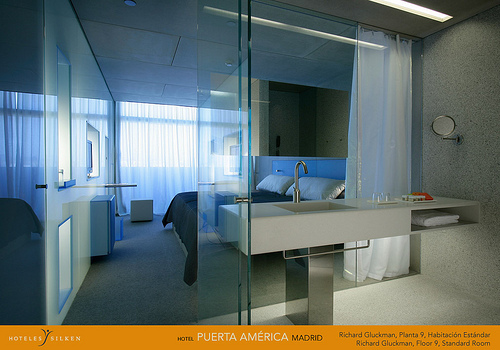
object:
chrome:
[293, 160, 309, 204]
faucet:
[292, 160, 308, 203]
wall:
[447, 50, 480, 78]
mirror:
[432, 115, 456, 135]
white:
[412, 210, 460, 227]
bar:
[283, 239, 370, 259]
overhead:
[376, 26, 450, 46]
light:
[370, 0, 454, 23]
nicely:
[177, 193, 266, 233]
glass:
[208, 16, 261, 70]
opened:
[195, 26, 246, 230]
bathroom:
[250, 56, 500, 325]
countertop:
[357, 198, 404, 208]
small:
[430, 115, 456, 138]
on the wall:
[429, 116, 464, 146]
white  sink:
[272, 201, 357, 213]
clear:
[60, 144, 71, 169]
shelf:
[57, 179, 76, 192]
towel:
[412, 210, 460, 227]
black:
[173, 194, 193, 222]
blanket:
[161, 190, 292, 286]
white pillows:
[256, 175, 347, 200]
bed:
[159, 174, 345, 287]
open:
[137, 20, 240, 233]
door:
[197, 0, 244, 325]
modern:
[0, 0, 500, 326]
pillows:
[256, 174, 300, 195]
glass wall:
[0, 0, 114, 325]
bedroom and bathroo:
[0, 0, 500, 325]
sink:
[271, 201, 357, 213]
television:
[86, 140, 93, 174]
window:
[120, 101, 199, 167]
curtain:
[118, 103, 242, 216]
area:
[275, 151, 355, 233]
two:
[256, 173, 345, 200]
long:
[293, 160, 308, 203]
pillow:
[285, 176, 346, 199]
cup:
[35, 184, 48, 190]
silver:
[235, 196, 254, 205]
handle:
[35, 184, 48, 190]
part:
[354, 22, 412, 51]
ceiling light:
[368, 0, 454, 23]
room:
[0, 0, 500, 325]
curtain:
[341, 25, 411, 283]